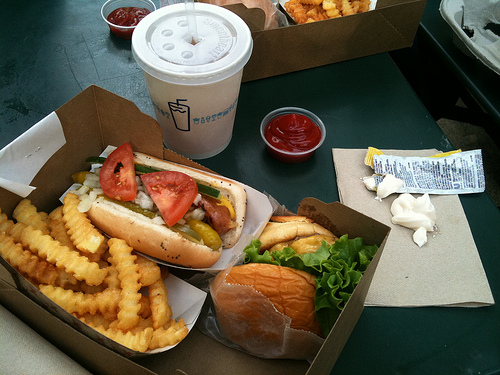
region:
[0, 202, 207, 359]
An order of french fries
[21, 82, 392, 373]
A cardboard box with food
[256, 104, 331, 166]
Plastic condiment cup with ketchup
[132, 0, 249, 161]
Cup with plastic cover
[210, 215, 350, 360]
Cheeseburger on a bun with lots of lettuce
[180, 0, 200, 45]
A clear straw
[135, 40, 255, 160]
A cup with a drawing of a drink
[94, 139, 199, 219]
tomato slices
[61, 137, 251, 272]
sausage sandwich with peppers onions, mustard and tomatoes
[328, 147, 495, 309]
A napkin with mayo on it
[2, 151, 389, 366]
Appetizing lunch cardboard box.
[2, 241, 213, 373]
Wide golden deep fried.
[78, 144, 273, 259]
Smoothed veggies bread bun.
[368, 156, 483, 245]
Foil packed mayo condiment.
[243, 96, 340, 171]
One serving cup ketchup.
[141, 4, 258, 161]
Drink cup plastic hole straw.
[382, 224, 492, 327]
Use brown paper napkin.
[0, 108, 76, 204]
Meal receipt stapled side box.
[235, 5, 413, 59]
Another meal brown box.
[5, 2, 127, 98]
Table surface green plastic.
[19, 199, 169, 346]
Basket of french fries.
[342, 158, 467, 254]
Dab of mayonaisse on a napkin.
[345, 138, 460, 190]
Mayonaisse and mustard packet.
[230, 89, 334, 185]
Silver cup of ketchup.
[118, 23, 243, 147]
Cup with straw in it.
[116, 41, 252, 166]
White cup with blue writing.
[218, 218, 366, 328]
Hamburger bun with lettuce.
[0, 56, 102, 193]
White receipt stapled to box.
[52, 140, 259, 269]
Hot dog on a bun with tomatoes on it.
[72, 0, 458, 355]
Food on a table.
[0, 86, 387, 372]
Card board box full of food.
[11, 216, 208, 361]
French fries in white container inside cardboard box.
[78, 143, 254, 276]
Hot dog in white container inside cardboard box.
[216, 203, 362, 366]
Hamburger inside cardboard box.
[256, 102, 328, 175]
Small plastic cup of ketchup.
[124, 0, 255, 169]
White paper cup with something to drink.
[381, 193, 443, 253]
Dollop of mayonnaise on napkin.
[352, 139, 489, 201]
Empty packet of mayonnaise.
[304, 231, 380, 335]
Green lettuce on hamburger.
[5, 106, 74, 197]
Bill stapled to side of cardboard box.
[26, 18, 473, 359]
lunch meal on a table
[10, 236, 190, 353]
ridged french fries in paper container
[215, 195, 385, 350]
cheeseberger with lettuce in waxed paper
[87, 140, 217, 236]
cut tomato halves on hot dog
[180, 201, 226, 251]
pickle at the end of the bun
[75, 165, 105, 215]
diced white onion next to tomato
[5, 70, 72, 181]
paper stapled to side of box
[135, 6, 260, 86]
straw though plastic lid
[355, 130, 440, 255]
condiment squeezed onto plate napkin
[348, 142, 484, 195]
flat and torn packet with sauce on it